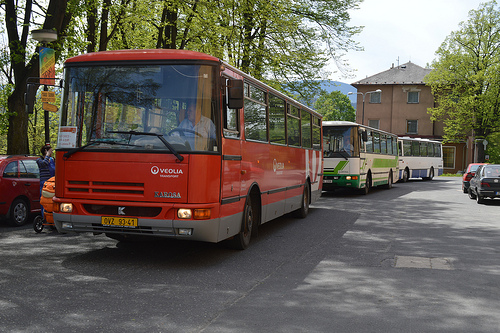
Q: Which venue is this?
A: This is a street.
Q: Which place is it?
A: It is a street.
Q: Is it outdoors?
A: Yes, it is outdoors.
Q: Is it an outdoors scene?
A: Yes, it is outdoors.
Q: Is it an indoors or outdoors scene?
A: It is outdoors.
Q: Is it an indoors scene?
A: No, it is outdoors.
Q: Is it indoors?
A: No, it is outdoors.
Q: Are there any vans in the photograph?
A: No, there are no vans.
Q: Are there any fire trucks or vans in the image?
A: No, there are no vans or fire trucks.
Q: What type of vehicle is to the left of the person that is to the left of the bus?
A: The vehicle is a car.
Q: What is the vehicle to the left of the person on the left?
A: The vehicle is a car.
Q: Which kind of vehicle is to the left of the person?
A: The vehicle is a car.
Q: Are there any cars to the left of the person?
A: Yes, there is a car to the left of the person.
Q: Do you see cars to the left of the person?
A: Yes, there is a car to the left of the person.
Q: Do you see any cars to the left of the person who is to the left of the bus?
A: Yes, there is a car to the left of the person.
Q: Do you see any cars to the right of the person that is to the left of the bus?
A: No, the car is to the left of the person.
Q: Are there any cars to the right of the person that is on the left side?
A: No, the car is to the left of the person.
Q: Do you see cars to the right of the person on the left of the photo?
A: No, the car is to the left of the person.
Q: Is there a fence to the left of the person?
A: No, there is a car to the left of the person.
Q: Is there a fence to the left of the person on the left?
A: No, there is a car to the left of the person.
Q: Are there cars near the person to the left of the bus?
A: Yes, there is a car near the person.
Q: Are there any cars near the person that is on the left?
A: Yes, there is a car near the person.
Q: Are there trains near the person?
A: No, there is a car near the person.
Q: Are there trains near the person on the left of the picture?
A: No, there is a car near the person.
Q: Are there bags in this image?
A: No, there are no bags.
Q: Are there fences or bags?
A: No, there are no bags or fences.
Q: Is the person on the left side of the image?
A: Yes, the person is on the left of the image.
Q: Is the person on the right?
A: No, the person is on the left of the image.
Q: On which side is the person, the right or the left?
A: The person is on the left of the image.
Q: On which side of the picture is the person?
A: The person is on the left of the image.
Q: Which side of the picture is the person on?
A: The person is on the left of the image.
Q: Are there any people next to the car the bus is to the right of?
A: Yes, there is a person next to the car.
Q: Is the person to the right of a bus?
A: No, the person is to the left of a bus.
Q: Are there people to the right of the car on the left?
A: Yes, there is a person to the right of the car.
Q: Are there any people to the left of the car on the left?
A: No, the person is to the right of the car.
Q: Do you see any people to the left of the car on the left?
A: No, the person is to the right of the car.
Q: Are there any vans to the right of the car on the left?
A: No, there is a person to the right of the car.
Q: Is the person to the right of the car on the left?
A: Yes, the person is to the right of the car.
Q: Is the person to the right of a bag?
A: No, the person is to the right of the car.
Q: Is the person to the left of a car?
A: No, the person is to the right of a car.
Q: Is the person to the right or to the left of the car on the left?
A: The person is to the right of the car.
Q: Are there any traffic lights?
A: No, there are no traffic lights.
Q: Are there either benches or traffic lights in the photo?
A: No, there are no traffic lights or benches.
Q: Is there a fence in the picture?
A: No, there are no fences.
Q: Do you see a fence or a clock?
A: No, there are no fences or clocks.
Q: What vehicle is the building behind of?
A: The building is behind the bus.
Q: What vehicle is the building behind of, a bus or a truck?
A: The building is behind a bus.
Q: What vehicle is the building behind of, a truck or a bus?
A: The building is behind a bus.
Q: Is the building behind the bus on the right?
A: Yes, the building is behind the bus.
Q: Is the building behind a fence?
A: No, the building is behind the bus.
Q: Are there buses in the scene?
A: Yes, there is a bus.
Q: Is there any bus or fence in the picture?
A: Yes, there is a bus.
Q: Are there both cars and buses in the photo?
A: Yes, there are both a bus and a car.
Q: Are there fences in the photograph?
A: No, there are no fences.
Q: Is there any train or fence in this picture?
A: No, there are no fences or trains.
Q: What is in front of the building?
A: The bus is in front of the building.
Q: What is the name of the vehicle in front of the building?
A: The vehicle is a bus.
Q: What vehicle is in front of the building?
A: The vehicle is a bus.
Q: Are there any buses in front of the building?
A: Yes, there is a bus in front of the building.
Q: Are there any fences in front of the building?
A: No, there is a bus in front of the building.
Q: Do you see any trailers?
A: No, there are no trailers.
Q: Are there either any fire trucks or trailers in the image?
A: No, there are no trailers or fire trucks.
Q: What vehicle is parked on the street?
A: The vehicle is a car.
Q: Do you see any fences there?
A: No, there are no fences.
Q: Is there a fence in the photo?
A: No, there are no fences.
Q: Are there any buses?
A: Yes, there is a bus.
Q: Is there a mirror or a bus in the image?
A: Yes, there is a bus.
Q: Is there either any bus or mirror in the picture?
A: Yes, there is a bus.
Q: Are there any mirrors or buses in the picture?
A: Yes, there is a bus.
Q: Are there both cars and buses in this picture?
A: Yes, there are both a bus and a car.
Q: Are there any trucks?
A: No, there are no trucks.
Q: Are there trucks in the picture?
A: No, there are no trucks.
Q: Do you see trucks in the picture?
A: No, there are no trucks.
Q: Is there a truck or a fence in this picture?
A: No, there are no trucks or fences.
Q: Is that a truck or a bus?
A: That is a bus.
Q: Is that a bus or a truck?
A: That is a bus.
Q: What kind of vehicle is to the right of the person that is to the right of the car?
A: The vehicle is a bus.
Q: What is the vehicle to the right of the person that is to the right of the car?
A: The vehicle is a bus.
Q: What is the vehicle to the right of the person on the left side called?
A: The vehicle is a bus.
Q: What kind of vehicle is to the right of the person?
A: The vehicle is a bus.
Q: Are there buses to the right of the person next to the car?
A: Yes, there is a bus to the right of the person.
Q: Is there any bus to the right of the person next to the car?
A: Yes, there is a bus to the right of the person.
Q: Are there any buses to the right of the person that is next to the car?
A: Yes, there is a bus to the right of the person.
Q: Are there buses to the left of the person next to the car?
A: No, the bus is to the right of the person.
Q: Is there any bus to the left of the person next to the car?
A: No, the bus is to the right of the person.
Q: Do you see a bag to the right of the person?
A: No, there is a bus to the right of the person.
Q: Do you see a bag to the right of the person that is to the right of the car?
A: No, there is a bus to the right of the person.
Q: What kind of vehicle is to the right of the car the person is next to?
A: The vehicle is a bus.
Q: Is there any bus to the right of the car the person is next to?
A: Yes, there is a bus to the right of the car.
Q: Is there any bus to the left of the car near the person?
A: No, the bus is to the right of the car.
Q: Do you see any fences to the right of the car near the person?
A: No, there is a bus to the right of the car.